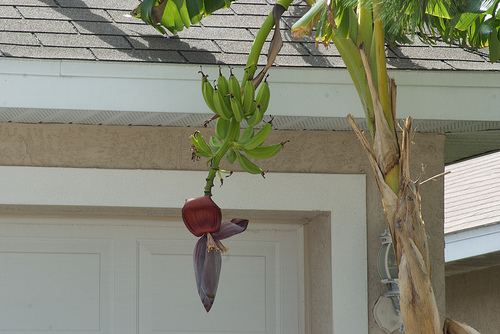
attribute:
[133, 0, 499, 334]
tree — banana tree, banana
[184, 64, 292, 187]
bananas — growing, hanging, green, bunch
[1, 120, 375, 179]
portion — tan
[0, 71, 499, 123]
portion — white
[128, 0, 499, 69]
leaves — green, bright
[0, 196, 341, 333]
door — white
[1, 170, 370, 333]
trim — white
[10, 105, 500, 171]
soffit — white, perforated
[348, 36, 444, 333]
bark — brown, flakey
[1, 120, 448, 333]
walls — tan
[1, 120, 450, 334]
wall — beige, stuccoed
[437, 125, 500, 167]
roof — next door